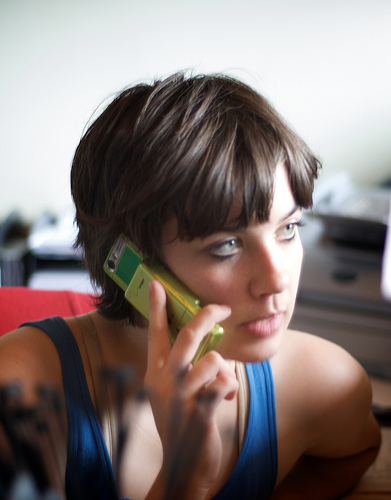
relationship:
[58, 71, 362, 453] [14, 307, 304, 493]
woman wearing shirt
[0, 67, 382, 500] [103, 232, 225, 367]
woman talking on cell phone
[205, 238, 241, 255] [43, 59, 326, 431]
eye on woman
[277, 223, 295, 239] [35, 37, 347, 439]
eye on woman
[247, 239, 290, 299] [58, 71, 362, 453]
nose on woman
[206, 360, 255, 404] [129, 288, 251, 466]
finger on hand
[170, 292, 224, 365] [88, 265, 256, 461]
finger on hand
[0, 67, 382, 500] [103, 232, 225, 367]
woman on cell phone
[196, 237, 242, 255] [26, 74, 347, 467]
eye on woman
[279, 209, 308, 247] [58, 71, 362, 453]
eye on woman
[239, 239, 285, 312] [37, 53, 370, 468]
nose on woman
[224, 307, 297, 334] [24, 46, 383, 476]
mouth on woman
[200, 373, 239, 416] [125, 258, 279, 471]
finger on hand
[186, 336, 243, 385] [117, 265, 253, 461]
finger on hand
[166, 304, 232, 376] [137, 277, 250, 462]
finger on hand